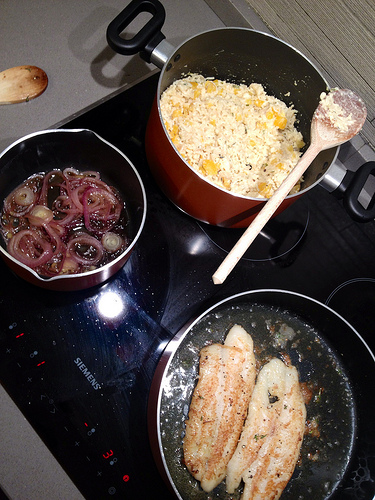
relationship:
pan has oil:
[140, 282, 374, 496] [213, 313, 349, 468]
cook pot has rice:
[106, 0, 375, 231] [169, 81, 305, 187]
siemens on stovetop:
[71, 352, 109, 397] [3, 65, 373, 497]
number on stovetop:
[37, 361, 46, 366] [3, 65, 373, 497]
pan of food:
[140, 282, 374, 496] [175, 313, 324, 500]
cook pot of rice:
[106, 0, 375, 231] [158, 72, 313, 200]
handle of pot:
[95, 1, 170, 55] [105, 1, 372, 228]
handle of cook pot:
[317, 156, 374, 221] [102, 2, 374, 248]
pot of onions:
[1, 126, 148, 292] [5, 165, 113, 257]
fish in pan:
[183, 326, 305, 493] [140, 282, 374, 496]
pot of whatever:
[1, 126, 148, 292] [157, 67, 312, 200]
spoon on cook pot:
[210, 76, 369, 324] [106, 0, 375, 231]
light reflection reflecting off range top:
[91, 286, 131, 321] [6, 42, 374, 489]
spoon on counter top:
[2, 53, 71, 103] [2, 1, 126, 131]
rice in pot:
[192, 74, 286, 178] [154, 9, 358, 174]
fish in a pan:
[183, 326, 305, 493] [140, 282, 374, 496]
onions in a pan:
[65, 235, 104, 265] [0, 127, 147, 293]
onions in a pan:
[101, 231, 122, 250] [0, 127, 147, 293]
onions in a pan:
[80, 188, 122, 234] [0, 127, 147, 293]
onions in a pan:
[34, 170, 77, 224] [0, 127, 147, 293]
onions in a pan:
[7, 229, 53, 266] [0, 127, 147, 293]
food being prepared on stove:
[160, 73, 304, 195] [1, 68, 366, 496]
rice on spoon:
[314, 95, 341, 125] [144, 77, 360, 305]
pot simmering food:
[1, 126, 148, 292] [192, 327, 324, 487]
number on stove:
[95, 443, 116, 458] [1, 68, 366, 496]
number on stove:
[31, 355, 48, 369] [50, 148, 374, 449]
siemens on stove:
[71, 352, 109, 397] [1, 68, 366, 496]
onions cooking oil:
[0, 152, 121, 273] [47, 186, 65, 205]